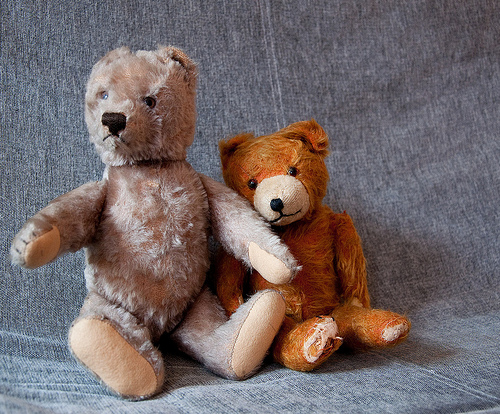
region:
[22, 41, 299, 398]
A light brown teddy bear.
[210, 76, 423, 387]
Small reddish teddy bear.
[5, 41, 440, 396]
Two teddy bears sitting together.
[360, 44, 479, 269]
Blue cloth the bears are sitting on.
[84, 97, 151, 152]
Cute black nose on a teddy bear.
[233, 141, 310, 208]
Bright shiny eyes on a teddy bear.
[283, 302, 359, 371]
The chewed foot of the teddy bear.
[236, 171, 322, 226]
Smiling mouth on the teddy bear.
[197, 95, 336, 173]
Floppy ears on the stuffed bear.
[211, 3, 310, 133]
Seam in the cloth.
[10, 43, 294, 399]
light brown teddy bear on the left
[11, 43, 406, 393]
two teddy bears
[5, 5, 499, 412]
gray cloth backdrop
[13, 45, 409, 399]
two bears sitting on gray cloth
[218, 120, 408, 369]
orange teddy bear on the right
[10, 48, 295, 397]
the bigger of two teddy bears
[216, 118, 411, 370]
the smaller teddy bear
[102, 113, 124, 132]
the left bear's brown nose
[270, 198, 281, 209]
the right bear's black nose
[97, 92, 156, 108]
the left bear's eyes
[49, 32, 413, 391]
two teddy bears sitting up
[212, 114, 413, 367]
one small teddy bear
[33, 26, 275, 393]
one large teddy bear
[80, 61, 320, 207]
teddy bears have eyes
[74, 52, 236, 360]
teddy bear is brown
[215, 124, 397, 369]
teddy bear is orange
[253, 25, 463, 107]
gray blanket behind the bears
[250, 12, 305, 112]
blanket has white stiching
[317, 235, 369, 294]
bear has long fur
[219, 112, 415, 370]
orange bear is on the right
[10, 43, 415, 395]
Two old teddy bears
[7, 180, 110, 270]
A teddy bear's arm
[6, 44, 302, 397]
A tan teddy bear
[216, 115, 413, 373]
A reddish brown teddy bear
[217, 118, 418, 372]
A worn out teddy bear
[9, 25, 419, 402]
Two teddy bears sitting on a couch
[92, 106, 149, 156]
A teddy bear nose and mouth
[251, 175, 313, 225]
A teddy bear muzzle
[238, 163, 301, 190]
Two teddy bear eyes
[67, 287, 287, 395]
Two teddy bear feet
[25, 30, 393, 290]
two stuffed bears in the room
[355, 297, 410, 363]
foot of the bear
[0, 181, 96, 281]
arm of the bear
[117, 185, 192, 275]
body of the bear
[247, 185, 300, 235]
nose of the bear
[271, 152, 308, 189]
eye of the bear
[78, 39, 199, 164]
head of the bear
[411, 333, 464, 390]
shadow next to bear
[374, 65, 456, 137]
wall behind the bear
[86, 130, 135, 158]
mouth of the bear